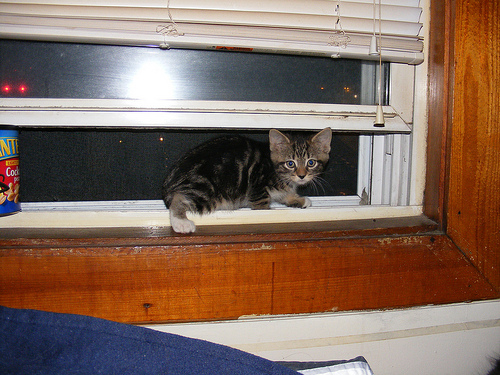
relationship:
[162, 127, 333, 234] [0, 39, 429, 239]
cat sitting in window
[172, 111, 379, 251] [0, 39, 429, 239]
cat sitting under window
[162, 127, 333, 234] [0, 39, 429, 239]
cat sitting under window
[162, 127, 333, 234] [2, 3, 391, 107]
cat sitting under window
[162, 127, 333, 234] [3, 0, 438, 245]
cat sitting under window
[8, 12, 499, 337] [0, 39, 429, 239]
frame around window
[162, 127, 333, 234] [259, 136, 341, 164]
cat has eyes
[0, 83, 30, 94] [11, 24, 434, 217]
lights outside window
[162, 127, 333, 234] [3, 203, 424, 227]
cat sitting on windowsill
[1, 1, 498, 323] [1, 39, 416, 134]
wood on side of window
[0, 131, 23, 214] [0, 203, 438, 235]
can of nuts on windowsill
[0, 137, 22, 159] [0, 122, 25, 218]
brand name on can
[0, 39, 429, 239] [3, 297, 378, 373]
window near bedding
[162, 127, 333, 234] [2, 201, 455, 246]
cat on sill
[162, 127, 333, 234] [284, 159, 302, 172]
cat has eye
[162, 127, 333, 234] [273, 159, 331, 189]
cat has whiskers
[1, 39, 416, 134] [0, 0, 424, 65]
window has blinds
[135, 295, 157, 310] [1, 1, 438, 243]
knot on windowsill